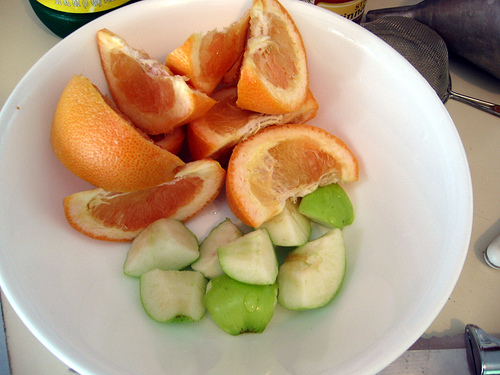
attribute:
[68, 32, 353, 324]
fruit — old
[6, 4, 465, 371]
plate — white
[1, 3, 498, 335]
counter — beig